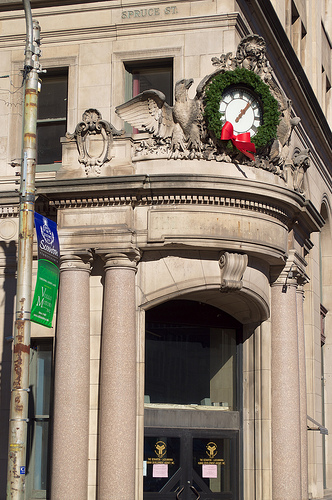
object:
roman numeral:
[238, 89, 242, 98]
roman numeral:
[229, 90, 234, 99]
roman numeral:
[221, 99, 230, 105]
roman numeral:
[252, 124, 258, 132]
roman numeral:
[217, 111, 225, 115]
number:
[252, 112, 265, 121]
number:
[250, 103, 259, 112]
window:
[115, 44, 182, 144]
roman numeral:
[236, 90, 247, 99]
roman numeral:
[229, 91, 235, 100]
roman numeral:
[253, 117, 261, 121]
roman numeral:
[248, 124, 257, 134]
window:
[192, 436, 235, 493]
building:
[0, 0, 330, 498]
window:
[22, 65, 68, 163]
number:
[251, 124, 259, 133]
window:
[139, 287, 272, 415]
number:
[216, 108, 226, 116]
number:
[228, 93, 235, 100]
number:
[237, 89, 243, 99]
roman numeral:
[251, 112, 263, 121]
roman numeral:
[227, 90, 236, 99]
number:
[236, 92, 245, 101]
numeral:
[219, 113, 226, 123]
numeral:
[251, 121, 260, 129]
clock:
[203, 72, 277, 156]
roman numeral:
[245, 96, 253, 106]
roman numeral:
[226, 85, 236, 101]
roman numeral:
[236, 89, 245, 99]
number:
[219, 94, 230, 107]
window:
[143, 423, 181, 499]